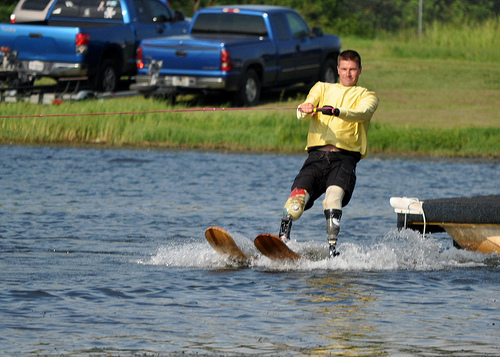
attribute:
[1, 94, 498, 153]
grass — Green 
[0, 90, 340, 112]
rope — red 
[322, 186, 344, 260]
prosthetic leg — white , grey, black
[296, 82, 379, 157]
top — yellow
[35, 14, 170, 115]
blue truck — blue , parked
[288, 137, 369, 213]
shorts — black 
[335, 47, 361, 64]
hair — short 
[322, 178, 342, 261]
prosthetic leg — prosthetic 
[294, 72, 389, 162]
shirt — yellow 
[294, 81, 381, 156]
yellow shirt — yellow 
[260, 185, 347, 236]
legs — proshetic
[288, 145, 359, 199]
shorts — black 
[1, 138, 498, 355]
water — large 